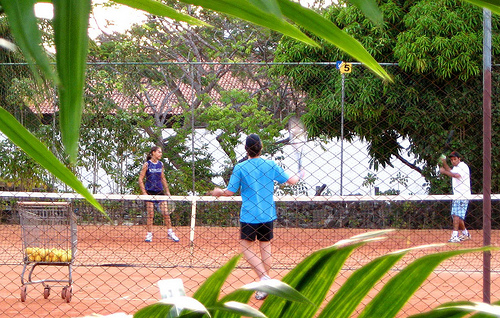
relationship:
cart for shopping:
[17, 198, 77, 307] [15, 197, 78, 293]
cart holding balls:
[17, 198, 77, 307] [24, 242, 75, 265]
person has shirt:
[216, 133, 305, 274] [228, 157, 289, 221]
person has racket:
[216, 133, 305, 274] [292, 148, 317, 187]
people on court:
[142, 142, 477, 246] [32, 219, 498, 309]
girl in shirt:
[141, 147, 179, 243] [140, 161, 170, 202]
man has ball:
[437, 149, 478, 241] [438, 154, 448, 161]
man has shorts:
[437, 149, 478, 241] [448, 195, 474, 220]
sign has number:
[341, 63, 352, 74] [341, 64, 351, 75]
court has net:
[32, 219, 498, 309] [7, 191, 500, 273]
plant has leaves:
[5, 3, 136, 233] [49, 8, 92, 163]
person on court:
[216, 133, 305, 274] [32, 219, 498, 309]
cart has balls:
[17, 198, 77, 307] [24, 242, 75, 265]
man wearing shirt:
[437, 149, 478, 241] [446, 163, 478, 203]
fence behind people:
[96, 72, 353, 126] [142, 142, 477, 246]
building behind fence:
[25, 55, 412, 189] [96, 72, 353, 126]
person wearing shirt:
[216, 133, 305, 274] [228, 157, 289, 221]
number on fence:
[341, 64, 351, 75] [96, 72, 353, 126]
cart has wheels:
[17, 198, 77, 307] [20, 281, 77, 302]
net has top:
[7, 191, 500, 273] [3, 187, 204, 205]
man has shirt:
[437, 149, 478, 241] [446, 163, 478, 203]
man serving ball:
[437, 149, 478, 241] [438, 154, 448, 161]